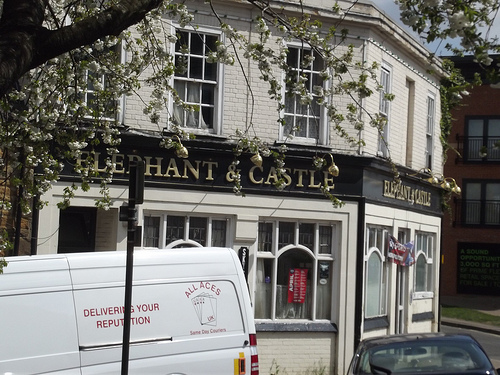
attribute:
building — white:
[19, 31, 439, 311]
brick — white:
[226, 93, 243, 118]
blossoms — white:
[92, 63, 114, 94]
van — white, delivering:
[6, 250, 263, 370]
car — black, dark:
[348, 325, 479, 374]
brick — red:
[450, 162, 468, 178]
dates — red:
[287, 264, 309, 306]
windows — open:
[172, 26, 329, 143]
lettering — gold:
[71, 168, 341, 179]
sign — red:
[278, 258, 313, 312]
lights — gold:
[419, 166, 463, 197]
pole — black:
[124, 159, 128, 370]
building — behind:
[445, 63, 497, 308]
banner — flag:
[361, 226, 445, 271]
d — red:
[83, 310, 90, 317]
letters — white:
[242, 246, 249, 260]